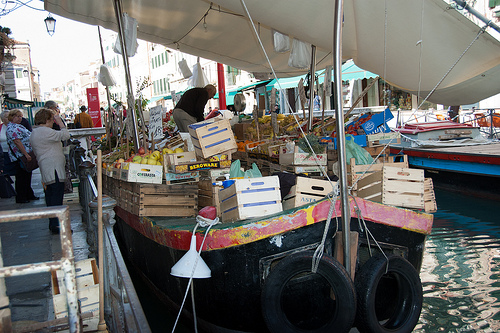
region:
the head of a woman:
[34, 105, 59, 129]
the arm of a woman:
[41, 110, 74, 142]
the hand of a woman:
[23, 150, 35, 162]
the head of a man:
[202, 79, 219, 104]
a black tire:
[255, 238, 359, 331]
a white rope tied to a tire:
[306, 181, 344, 273]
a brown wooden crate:
[214, 170, 285, 237]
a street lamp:
[41, 7, 60, 38]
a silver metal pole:
[328, 1, 348, 230]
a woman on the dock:
[23, 99, 80, 245]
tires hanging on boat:
[258, 232, 428, 330]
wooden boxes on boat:
[125, 112, 441, 243]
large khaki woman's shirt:
[36, 120, 80, 191]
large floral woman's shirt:
[5, 117, 42, 174]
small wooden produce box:
[349, 147, 434, 214]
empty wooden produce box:
[361, 153, 431, 221]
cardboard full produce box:
[111, 148, 166, 190]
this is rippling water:
[442, 247, 496, 316]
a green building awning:
[224, 57, 396, 108]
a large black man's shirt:
[163, 83, 225, 126]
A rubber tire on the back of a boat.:
[349, 242, 424, 331]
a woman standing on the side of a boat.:
[23, 108, 74, 224]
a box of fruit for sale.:
[115, 153, 162, 190]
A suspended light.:
[38, 15, 58, 39]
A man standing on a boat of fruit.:
[156, 60, 231, 139]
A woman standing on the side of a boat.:
[26, 107, 71, 232]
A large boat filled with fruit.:
[103, 137, 438, 332]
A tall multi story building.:
[149, 24, 176, 116]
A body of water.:
[396, 203, 498, 330]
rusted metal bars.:
[0, 201, 83, 332]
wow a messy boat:
[109, 54, 489, 274]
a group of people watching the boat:
[12, 88, 111, 191]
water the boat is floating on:
[456, 227, 491, 274]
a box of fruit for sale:
[116, 142, 203, 189]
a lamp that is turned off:
[41, 17, 83, 47]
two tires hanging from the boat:
[273, 247, 450, 331]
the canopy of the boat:
[167, 1, 477, 90]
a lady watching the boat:
[4, 101, 53, 203]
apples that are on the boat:
[114, 142, 206, 172]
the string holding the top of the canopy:
[325, 27, 448, 140]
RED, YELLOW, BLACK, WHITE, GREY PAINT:
[249, 219, 319, 248]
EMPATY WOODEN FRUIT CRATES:
[356, 165, 433, 204]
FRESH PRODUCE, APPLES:
[109, 156, 167, 181]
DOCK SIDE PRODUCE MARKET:
[33, 99, 180, 221]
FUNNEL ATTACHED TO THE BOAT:
[170, 204, 221, 287]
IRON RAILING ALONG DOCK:
[78, 160, 137, 332]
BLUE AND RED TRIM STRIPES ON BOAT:
[436, 150, 499, 177]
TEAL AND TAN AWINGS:
[343, 60, 390, 85]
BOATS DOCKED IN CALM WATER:
[379, 169, 499, 233]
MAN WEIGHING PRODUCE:
[173, 74, 250, 156]